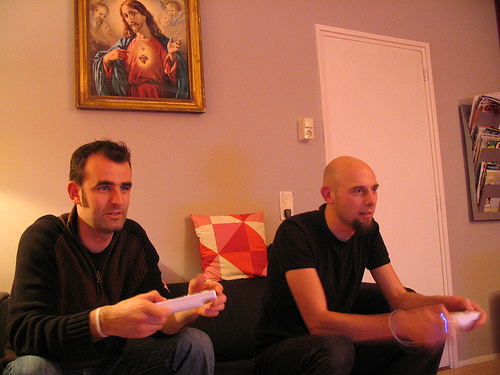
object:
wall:
[4, 7, 498, 305]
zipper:
[95, 271, 102, 283]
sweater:
[6, 215, 174, 355]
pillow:
[188, 210, 268, 283]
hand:
[105, 48, 130, 60]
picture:
[75, 0, 207, 114]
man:
[253, 154, 486, 375]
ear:
[320, 185, 333, 204]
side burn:
[78, 186, 90, 209]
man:
[0, 139, 227, 375]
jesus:
[91, 0, 190, 99]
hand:
[167, 37, 182, 54]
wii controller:
[154, 290, 217, 313]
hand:
[95, 291, 170, 340]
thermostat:
[298, 114, 314, 142]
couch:
[165, 276, 447, 374]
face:
[87, 166, 132, 231]